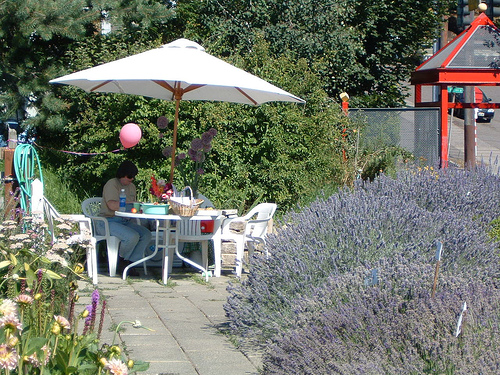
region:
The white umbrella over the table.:
[50, 38, 307, 110]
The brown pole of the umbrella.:
[159, 87, 183, 201]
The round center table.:
[110, 204, 215, 289]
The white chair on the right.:
[222, 197, 272, 284]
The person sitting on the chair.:
[100, 163, 152, 265]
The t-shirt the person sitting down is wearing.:
[106, 177, 144, 215]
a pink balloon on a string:
[55, 122, 140, 159]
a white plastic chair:
[223, 198, 278, 274]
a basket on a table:
[171, 186, 208, 214]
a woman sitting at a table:
[107, 161, 139, 260]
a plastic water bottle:
[114, 189, 130, 213]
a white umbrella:
[48, 35, 308, 107]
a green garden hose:
[13, 137, 45, 211]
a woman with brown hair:
[115, 163, 137, 180]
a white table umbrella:
[47, 37, 306, 107]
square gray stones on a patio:
[56, 270, 271, 374]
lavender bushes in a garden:
[229, 155, 498, 373]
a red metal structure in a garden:
[415, 15, 498, 167]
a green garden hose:
[13, 140, 44, 234]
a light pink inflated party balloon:
[121, 123, 141, 148]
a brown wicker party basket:
[170, 186, 203, 216]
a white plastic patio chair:
[225, 201, 276, 276]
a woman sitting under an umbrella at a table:
[91, 156, 153, 273]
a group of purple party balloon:
[154, 111, 218, 179]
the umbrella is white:
[49, 37, 314, 134]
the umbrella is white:
[42, 25, 310, 130]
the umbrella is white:
[42, 27, 316, 139]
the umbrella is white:
[52, 15, 321, 155]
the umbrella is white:
[46, 22, 286, 138]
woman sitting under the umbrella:
[65, 57, 268, 290]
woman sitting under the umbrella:
[52, 32, 220, 271]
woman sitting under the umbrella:
[85, 61, 191, 303]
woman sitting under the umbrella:
[70, 43, 170, 270]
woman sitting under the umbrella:
[62, 47, 180, 305]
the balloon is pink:
[112, 126, 144, 161]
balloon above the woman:
[110, 127, 147, 267]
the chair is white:
[232, 201, 273, 282]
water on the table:
[117, 189, 127, 216]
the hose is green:
[15, 145, 47, 196]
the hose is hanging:
[15, 140, 47, 206]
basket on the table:
[173, 184, 200, 221]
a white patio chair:
[205, 184, 295, 311]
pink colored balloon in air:
[116, 117, 150, 151]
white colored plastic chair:
[209, 194, 281, 271]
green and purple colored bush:
[231, 154, 487, 372]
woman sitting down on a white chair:
[96, 163, 157, 274]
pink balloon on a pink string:
[58, 120, 140, 156]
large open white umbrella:
[46, 35, 307, 105]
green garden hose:
[13, 143, 43, 216]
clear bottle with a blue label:
[117, 188, 126, 209]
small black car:
[446, 84, 494, 121]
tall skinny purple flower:
[89, 288, 99, 330]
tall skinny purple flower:
[81, 303, 91, 333]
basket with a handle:
[171, 185, 203, 216]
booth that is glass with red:
[408, 10, 499, 169]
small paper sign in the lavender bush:
[430, 238, 444, 297]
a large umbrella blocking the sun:
[48, 36, 308, 116]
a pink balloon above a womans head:
[115, 106, 142, 158]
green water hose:
[12, 132, 45, 233]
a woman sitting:
[97, 157, 157, 270]